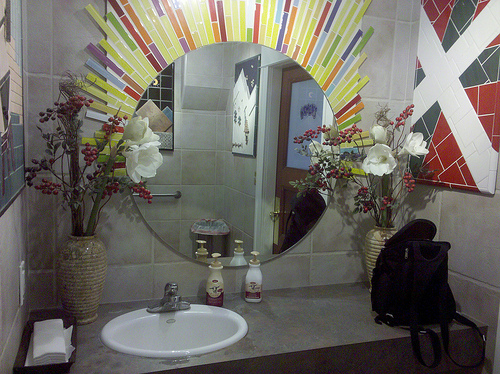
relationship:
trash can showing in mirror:
[190, 217, 232, 258] [123, 41, 342, 270]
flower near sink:
[120, 140, 164, 184] [100, 302, 248, 359]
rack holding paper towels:
[12, 308, 78, 372] [24, 318, 75, 367]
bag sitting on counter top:
[371, 218, 488, 369] [13, 281, 488, 374]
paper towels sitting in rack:
[24, 318, 75, 367] [12, 308, 78, 372]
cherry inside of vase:
[409, 178, 414, 184] [363, 223, 399, 291]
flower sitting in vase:
[122, 115, 161, 146] [55, 233, 109, 326]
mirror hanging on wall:
[123, 41, 342, 270] [27, 1, 415, 312]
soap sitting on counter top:
[204, 252, 223, 307] [13, 281, 488, 374]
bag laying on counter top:
[371, 218, 488, 369] [13, 281, 488, 374]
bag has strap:
[371, 218, 488, 369] [440, 311, 487, 369]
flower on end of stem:
[120, 140, 164, 184] [84, 156, 116, 237]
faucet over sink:
[146, 281, 191, 315] [100, 302, 248, 359]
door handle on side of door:
[268, 209, 279, 223] [271, 62, 325, 254]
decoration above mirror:
[80, 0, 375, 179] [123, 41, 342, 270]